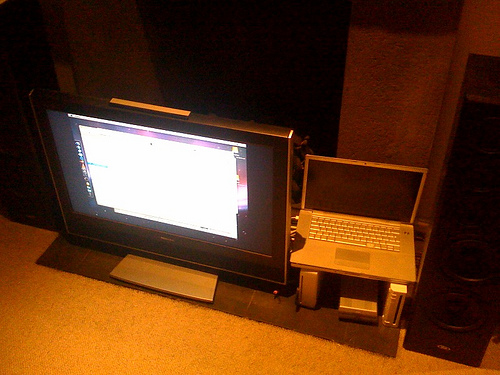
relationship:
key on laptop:
[335, 237, 366, 247] [291, 153, 428, 286]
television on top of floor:
[29, 90, 294, 304] [0, 215, 499, 374]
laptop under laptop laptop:
[291, 153, 428, 286] [291, 153, 428, 286]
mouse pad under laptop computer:
[333, 248, 373, 265] [95, 248, 238, 318]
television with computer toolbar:
[29, 90, 294, 304] [136, 204, 239, 305]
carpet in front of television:
[5, 221, 493, 372] [29, 90, 294, 304]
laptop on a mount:
[291, 153, 428, 286] [218, 241, 431, 353]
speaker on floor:
[402, 51, 496, 368] [148, 324, 370, 363]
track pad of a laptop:
[311, 298, 394, 340] [291, 153, 428, 286]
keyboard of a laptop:
[307, 210, 399, 255] [269, 224, 439, 257]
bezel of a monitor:
[93, 239, 227, 290] [45, 108, 273, 261]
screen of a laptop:
[54, 93, 241, 268] [291, 153, 428, 286]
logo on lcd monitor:
[158, 234, 175, 244] [87, 120, 224, 240]